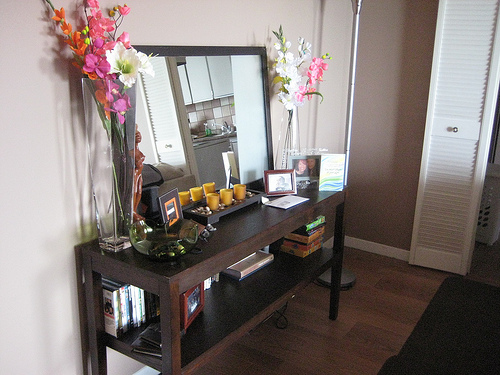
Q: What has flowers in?
A: The crystal vase.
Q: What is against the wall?
A: The framed mirror.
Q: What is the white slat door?
A: Closet.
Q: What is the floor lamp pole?
A: Metal.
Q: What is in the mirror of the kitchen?
A: The reflection.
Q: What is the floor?
A: Wooden.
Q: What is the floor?
A: Wooden.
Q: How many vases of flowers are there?
A: Two.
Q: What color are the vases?
A: Clear.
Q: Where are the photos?
A: Shelf.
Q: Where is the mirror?
A: Wall.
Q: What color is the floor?
A: Brown.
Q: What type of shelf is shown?
A: Wood.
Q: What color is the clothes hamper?
A: White.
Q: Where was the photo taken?
A: In a room.